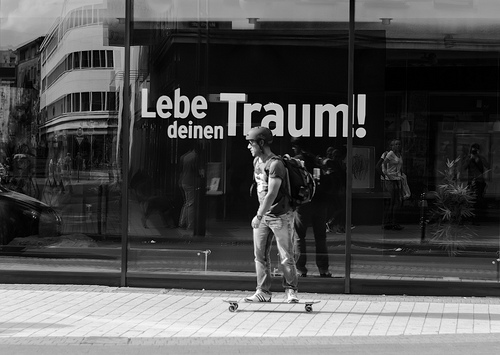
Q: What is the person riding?
A: A skateboard.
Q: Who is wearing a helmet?
A: The skateboarder.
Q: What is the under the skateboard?
A: Brick sidewalk.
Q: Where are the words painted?
A: On the windows.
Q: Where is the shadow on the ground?
A: In back of the skateboarder.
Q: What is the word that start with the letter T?
A: TRAUM.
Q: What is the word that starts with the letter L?
A: LEBE.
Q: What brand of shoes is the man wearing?
A: Adidas.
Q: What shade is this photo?
A: Black and white.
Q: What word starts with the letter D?
A: DEINEN.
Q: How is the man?
A: In motion.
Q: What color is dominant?
A: Black.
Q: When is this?
A: Daytime.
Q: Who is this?
A: Skater.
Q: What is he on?
A: Skateboard.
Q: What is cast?
A: Shadows.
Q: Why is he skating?
A: Fun.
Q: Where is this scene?
A: On a sidewalk.